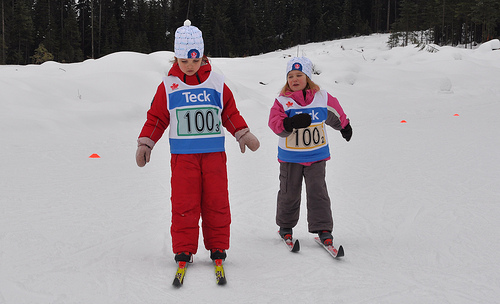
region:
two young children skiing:
[121, 10, 384, 294]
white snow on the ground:
[15, 188, 157, 287]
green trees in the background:
[10, 5, 168, 47]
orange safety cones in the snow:
[85, 148, 110, 167]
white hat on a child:
[170, 7, 213, 69]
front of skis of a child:
[162, 263, 249, 293]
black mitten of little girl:
[274, 112, 320, 134]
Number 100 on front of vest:
[177, 108, 217, 133]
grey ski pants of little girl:
[267, 161, 339, 240]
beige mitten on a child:
[129, 135, 162, 177]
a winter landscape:
[17, 8, 477, 300]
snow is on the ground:
[30, 42, 485, 299]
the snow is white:
[13, 44, 496, 295]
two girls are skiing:
[136, 16, 363, 293]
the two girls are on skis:
[131, 16, 376, 293]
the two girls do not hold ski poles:
[139, 16, 381, 301]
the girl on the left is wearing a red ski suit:
[128, 14, 262, 296]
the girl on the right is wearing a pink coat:
[267, 47, 361, 272]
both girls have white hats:
[129, 25, 376, 281]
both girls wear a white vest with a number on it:
[156, 71, 344, 170]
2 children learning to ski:
[59, 10, 428, 275]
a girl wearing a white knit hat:
[170, 21, 225, 83]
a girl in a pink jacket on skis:
[256, 47, 365, 258]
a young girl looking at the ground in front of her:
[132, 17, 253, 284]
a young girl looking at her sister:
[253, 42, 355, 165]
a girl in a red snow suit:
[152, 26, 256, 267]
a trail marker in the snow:
[68, 130, 119, 185]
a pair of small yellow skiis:
[153, 245, 238, 290]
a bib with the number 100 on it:
[170, 92, 230, 150]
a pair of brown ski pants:
[274, 159, 371, 241]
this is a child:
[138, 17, 249, 287]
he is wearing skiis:
[165, 260, 232, 291]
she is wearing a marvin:
[174, 25, 203, 55]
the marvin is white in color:
[180, 31, 199, 52]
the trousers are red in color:
[181, 162, 221, 242]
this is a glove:
[134, 144, 150, 164]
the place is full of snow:
[387, 140, 488, 299]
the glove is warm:
[133, 139, 152, 165]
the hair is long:
[305, 80, 318, 89]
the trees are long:
[16, 5, 142, 42]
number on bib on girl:
[180, 112, 225, 139]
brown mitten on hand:
[137, 143, 152, 168]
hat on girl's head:
[172, 21, 203, 56]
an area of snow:
[26, 181, 131, 269]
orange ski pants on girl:
[172, 155, 234, 247]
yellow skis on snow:
[175, 260, 227, 291]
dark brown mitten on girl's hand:
[282, 112, 315, 133]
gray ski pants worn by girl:
[280, 162, 329, 230]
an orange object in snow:
[74, 142, 108, 167]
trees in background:
[15, 26, 85, 58]